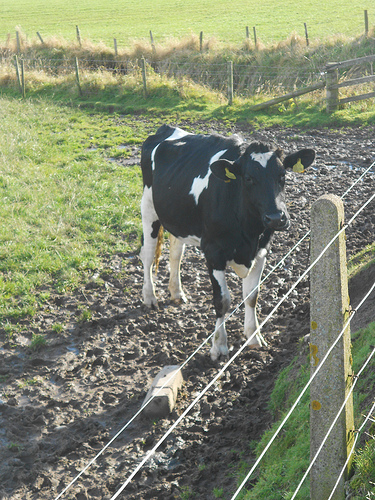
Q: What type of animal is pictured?
A: A cow.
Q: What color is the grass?
A: Green.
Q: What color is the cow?
A: Black and white.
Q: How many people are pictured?
A: Zero.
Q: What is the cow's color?
A: Black and white.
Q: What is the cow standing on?
A: Dirt.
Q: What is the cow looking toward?
A: The camera.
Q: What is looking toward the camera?
A: A cow.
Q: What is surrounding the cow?
A: A fence.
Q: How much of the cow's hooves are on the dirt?
A: Four.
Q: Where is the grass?
A: Behind the cow.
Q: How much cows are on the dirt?
A: One.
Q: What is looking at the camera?
A: A cow.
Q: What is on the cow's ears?
A: Yellow tags.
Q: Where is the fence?
A: In front of the cow.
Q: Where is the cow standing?
A: In the mud.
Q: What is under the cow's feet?
A: Mud.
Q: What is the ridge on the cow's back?
A: Spine.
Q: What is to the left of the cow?
A: A cinder block.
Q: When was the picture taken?
A: Daytime.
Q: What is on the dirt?
A: The cow.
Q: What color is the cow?
A: Black and white.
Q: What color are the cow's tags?
A: Yellow.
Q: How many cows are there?
A: One.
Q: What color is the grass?
A: Green.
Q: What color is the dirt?
A: Brown.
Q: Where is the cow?
A: On the dirt.